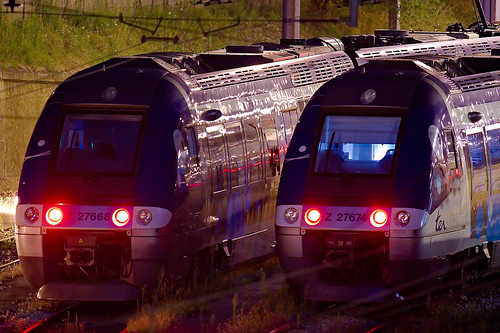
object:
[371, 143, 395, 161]
lights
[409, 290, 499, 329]
gravel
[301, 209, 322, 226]
light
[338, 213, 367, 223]
number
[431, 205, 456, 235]
ter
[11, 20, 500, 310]
train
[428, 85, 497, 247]
side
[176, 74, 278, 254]
side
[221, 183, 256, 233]
coloring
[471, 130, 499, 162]
coloring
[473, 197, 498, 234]
coloring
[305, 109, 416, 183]
windows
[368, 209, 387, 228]
light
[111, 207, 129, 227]
light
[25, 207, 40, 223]
light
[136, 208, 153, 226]
light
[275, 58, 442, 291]
train front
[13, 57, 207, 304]
train front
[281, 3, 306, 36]
pole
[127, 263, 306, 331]
grass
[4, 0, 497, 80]
hillside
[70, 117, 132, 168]
inside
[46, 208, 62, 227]
train lights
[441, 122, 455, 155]
window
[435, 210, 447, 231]
lettering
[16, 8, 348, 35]
wire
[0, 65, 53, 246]
grass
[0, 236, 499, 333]
railroad track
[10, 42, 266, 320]
keyboard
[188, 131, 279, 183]
reflection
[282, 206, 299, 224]
lights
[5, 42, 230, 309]
evergreen tree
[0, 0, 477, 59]
grass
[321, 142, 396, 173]
blue lights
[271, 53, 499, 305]
train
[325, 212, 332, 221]
letter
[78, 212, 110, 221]
numbers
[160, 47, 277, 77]
top